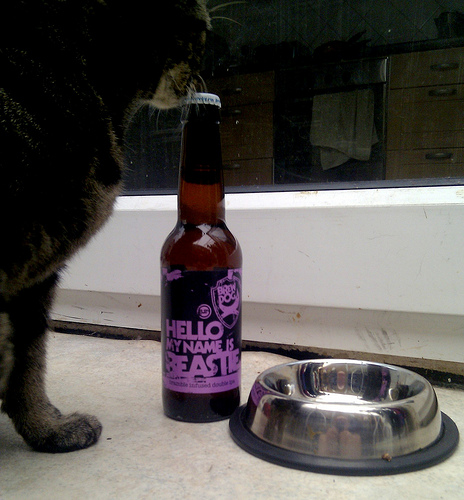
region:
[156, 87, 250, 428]
bottle of beer on table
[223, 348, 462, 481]
pet dish on ground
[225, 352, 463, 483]
pet dish is silver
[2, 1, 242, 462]
cat is standing by bottle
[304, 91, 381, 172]
reflection of towel in window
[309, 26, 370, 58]
reflection of pans in window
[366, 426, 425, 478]
a crumb of cat food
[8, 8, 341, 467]
a grey and black cat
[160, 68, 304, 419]
a bottle of dog brew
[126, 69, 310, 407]
a brown glass bottle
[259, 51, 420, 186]
a white hand towel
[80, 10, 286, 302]
a curious cat sniffing lid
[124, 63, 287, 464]
a brown bottle with purple writing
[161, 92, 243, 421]
beer says hello my name is beastie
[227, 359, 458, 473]
food bowl is black and silver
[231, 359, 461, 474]
food bowl is empty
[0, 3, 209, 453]
cat is sniffing a beer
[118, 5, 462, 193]
building has a window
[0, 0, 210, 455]
cat is black with wiskers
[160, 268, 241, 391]
beer label is purple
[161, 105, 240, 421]
beer bottle is dark brown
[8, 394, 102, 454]
cat has a gray and brown paw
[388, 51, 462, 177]
dresser is wooden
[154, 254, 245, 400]
A purple and black label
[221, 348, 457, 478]
A bowl is silver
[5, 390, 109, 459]
The paw of a cat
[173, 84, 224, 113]
The lid of a bottle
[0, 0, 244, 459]
A cat is sniffing a bottle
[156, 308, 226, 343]
The word "HELLO" on a label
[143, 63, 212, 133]
Whiskers on cat's face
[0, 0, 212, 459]
A cat is gray and black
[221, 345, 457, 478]
The bowl is round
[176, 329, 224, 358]
"NAME" written on a lable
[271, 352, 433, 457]
the dish is silver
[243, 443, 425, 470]
the base is rubber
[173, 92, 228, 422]
the bottle is brown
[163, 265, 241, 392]
the label is purple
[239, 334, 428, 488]
dish on the ground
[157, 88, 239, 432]
bottle on the ground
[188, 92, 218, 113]
lid on the bottle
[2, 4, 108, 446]
the cat is black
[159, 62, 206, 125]
the whiskers are white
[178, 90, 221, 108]
Grey cap of a bottle.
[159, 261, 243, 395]
Black label with purple writing on it.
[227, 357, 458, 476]
A silver cat dish with black ring around the bottom.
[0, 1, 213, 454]
A black and brown cat.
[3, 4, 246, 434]
the cat is sniffing the bottle cap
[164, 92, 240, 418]
a brown glass bottle with a grey cap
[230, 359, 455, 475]
the feeding dish is silver and black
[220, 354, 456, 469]
Silver cat dish on the floor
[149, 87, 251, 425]
Beer bottle on the floor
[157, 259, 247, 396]
Purple labeling on the bottle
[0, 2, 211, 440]
cat standing beside the bottle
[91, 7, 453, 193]
glass pane in the door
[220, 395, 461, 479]
black rim on dish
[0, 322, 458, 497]
beige carpeting on the floor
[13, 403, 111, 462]
paw on the cats foot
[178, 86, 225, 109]
silver colored cap on the bottle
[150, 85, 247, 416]
brown bottle of a drink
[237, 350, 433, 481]
silver and black food bowl